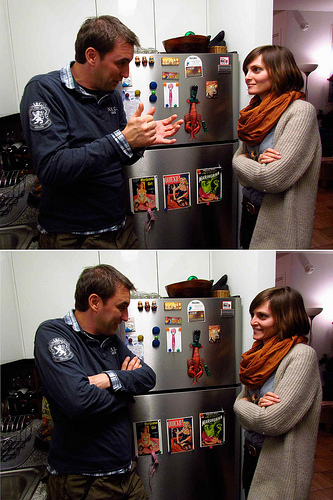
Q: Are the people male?
A: No, they are both male and female.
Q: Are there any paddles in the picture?
A: No, there are no paddles.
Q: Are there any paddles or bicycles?
A: No, there are no paddles or bicycles.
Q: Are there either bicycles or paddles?
A: No, there are no paddles or bicycles.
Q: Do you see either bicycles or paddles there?
A: No, there are no paddles or bicycles.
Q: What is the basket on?
A: The basket is on the freezer.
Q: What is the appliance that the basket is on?
A: The appliance is a refrigerator.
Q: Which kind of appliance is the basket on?
A: The basket is on the freezer.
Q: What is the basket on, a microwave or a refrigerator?
A: The basket is on a refrigerator.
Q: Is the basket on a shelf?
A: No, the basket is on a refrigerator.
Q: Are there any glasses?
A: No, there are no glasses.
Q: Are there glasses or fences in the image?
A: No, there are no glasses or fences.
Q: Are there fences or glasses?
A: No, there are no glasses or fences.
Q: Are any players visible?
A: No, there are no players.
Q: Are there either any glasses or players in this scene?
A: No, there are no players or glasses.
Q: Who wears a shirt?
A: The man wears a shirt.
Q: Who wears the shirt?
A: The man wears a shirt.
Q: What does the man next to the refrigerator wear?
A: The man wears a shirt.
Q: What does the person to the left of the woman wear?
A: The man wears a shirt.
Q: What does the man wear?
A: The man wears a shirt.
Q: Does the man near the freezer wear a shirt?
A: Yes, the man wears a shirt.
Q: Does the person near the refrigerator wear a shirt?
A: Yes, the man wears a shirt.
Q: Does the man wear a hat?
A: No, the man wears a shirt.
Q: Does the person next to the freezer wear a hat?
A: No, the man wears a shirt.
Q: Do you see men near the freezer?
A: Yes, there is a man near the freezer.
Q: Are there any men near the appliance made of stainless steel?
A: Yes, there is a man near the freezer.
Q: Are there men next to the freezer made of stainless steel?
A: Yes, there is a man next to the freezer.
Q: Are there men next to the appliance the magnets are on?
A: Yes, there is a man next to the freezer.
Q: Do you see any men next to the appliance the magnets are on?
A: Yes, there is a man next to the freezer.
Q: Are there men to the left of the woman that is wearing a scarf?
A: Yes, there is a man to the left of the woman.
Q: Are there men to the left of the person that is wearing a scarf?
A: Yes, there is a man to the left of the woman.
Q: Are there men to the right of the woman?
A: No, the man is to the left of the woman.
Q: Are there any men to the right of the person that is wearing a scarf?
A: No, the man is to the left of the woman.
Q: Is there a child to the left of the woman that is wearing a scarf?
A: No, there is a man to the left of the woman.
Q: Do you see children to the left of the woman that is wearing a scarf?
A: No, there is a man to the left of the woman.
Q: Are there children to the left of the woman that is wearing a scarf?
A: No, there is a man to the left of the woman.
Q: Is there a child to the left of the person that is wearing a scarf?
A: No, there is a man to the left of the woman.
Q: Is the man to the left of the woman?
A: Yes, the man is to the left of the woman.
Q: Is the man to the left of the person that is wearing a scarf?
A: Yes, the man is to the left of the woman.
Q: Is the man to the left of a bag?
A: No, the man is to the left of the woman.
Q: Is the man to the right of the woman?
A: No, the man is to the left of the woman.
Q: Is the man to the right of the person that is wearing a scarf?
A: No, the man is to the left of the woman.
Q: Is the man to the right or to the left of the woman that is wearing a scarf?
A: The man is to the left of the woman.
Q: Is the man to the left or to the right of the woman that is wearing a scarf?
A: The man is to the left of the woman.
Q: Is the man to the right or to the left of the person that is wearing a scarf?
A: The man is to the left of the woman.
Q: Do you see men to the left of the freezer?
A: Yes, there is a man to the left of the freezer.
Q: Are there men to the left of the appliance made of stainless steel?
A: Yes, there is a man to the left of the freezer.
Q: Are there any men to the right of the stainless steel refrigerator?
A: No, the man is to the left of the refrigerator.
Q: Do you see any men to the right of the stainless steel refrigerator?
A: No, the man is to the left of the refrigerator.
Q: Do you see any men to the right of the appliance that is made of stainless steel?
A: No, the man is to the left of the refrigerator.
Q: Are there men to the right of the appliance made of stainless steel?
A: No, the man is to the left of the refrigerator.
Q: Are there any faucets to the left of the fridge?
A: No, there is a man to the left of the fridge.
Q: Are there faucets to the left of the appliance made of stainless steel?
A: No, there is a man to the left of the fridge.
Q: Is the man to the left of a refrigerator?
A: Yes, the man is to the left of a refrigerator.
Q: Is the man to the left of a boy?
A: No, the man is to the left of a refrigerator.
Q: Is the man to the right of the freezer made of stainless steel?
A: No, the man is to the left of the fridge.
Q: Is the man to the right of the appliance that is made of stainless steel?
A: No, the man is to the left of the fridge.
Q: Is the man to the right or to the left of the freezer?
A: The man is to the left of the freezer.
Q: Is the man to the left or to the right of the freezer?
A: The man is to the left of the freezer.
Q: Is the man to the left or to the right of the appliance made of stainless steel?
A: The man is to the left of the freezer.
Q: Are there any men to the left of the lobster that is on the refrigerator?
A: Yes, there is a man to the left of the lobster.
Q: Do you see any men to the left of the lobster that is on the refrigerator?
A: Yes, there is a man to the left of the lobster.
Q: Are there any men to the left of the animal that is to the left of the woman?
A: Yes, there is a man to the left of the lobster.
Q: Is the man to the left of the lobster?
A: Yes, the man is to the left of the lobster.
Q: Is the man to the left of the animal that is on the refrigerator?
A: Yes, the man is to the left of the lobster.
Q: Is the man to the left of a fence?
A: No, the man is to the left of the lobster.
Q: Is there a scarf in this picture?
A: Yes, there is a scarf.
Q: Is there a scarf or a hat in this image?
A: Yes, there is a scarf.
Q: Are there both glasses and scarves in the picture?
A: No, there is a scarf but no glasses.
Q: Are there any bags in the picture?
A: No, there are no bags.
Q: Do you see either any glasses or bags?
A: No, there are no bags or glasses.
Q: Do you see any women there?
A: Yes, there is a woman.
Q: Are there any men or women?
A: Yes, there is a woman.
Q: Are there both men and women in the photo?
A: Yes, there are both a woman and a man.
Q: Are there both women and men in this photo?
A: Yes, there are both a woman and a man.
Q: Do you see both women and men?
A: Yes, there are both a woman and a man.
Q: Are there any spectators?
A: No, there are no spectators.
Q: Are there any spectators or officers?
A: No, there are no spectators or officers.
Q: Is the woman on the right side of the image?
A: Yes, the woman is on the right of the image.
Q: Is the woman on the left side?
A: No, the woman is on the right of the image.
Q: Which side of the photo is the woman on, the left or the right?
A: The woman is on the right of the image.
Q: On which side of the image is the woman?
A: The woman is on the right of the image.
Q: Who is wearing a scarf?
A: The woman is wearing a scarf.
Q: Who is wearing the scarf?
A: The woman is wearing a scarf.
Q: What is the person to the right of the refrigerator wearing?
A: The woman is wearing a scarf.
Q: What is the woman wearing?
A: The woman is wearing a scarf.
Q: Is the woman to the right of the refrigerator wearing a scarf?
A: Yes, the woman is wearing a scarf.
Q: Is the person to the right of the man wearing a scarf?
A: Yes, the woman is wearing a scarf.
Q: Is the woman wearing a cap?
A: No, the woman is wearing a scarf.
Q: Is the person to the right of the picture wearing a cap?
A: No, the woman is wearing a scarf.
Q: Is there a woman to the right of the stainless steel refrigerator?
A: Yes, there is a woman to the right of the fridge.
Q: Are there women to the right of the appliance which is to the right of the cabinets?
A: Yes, there is a woman to the right of the fridge.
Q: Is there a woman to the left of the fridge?
A: No, the woman is to the right of the fridge.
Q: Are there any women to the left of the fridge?
A: No, the woman is to the right of the fridge.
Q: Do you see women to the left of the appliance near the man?
A: No, the woman is to the right of the fridge.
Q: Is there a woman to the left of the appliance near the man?
A: No, the woman is to the right of the fridge.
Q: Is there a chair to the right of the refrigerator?
A: No, there is a woman to the right of the refrigerator.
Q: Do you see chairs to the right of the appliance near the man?
A: No, there is a woman to the right of the refrigerator.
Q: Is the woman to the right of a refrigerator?
A: Yes, the woman is to the right of a refrigerator.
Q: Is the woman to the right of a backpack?
A: No, the woman is to the right of a refrigerator.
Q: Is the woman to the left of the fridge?
A: No, the woman is to the right of the fridge.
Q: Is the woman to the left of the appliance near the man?
A: No, the woman is to the right of the fridge.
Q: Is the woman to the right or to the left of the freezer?
A: The woman is to the right of the freezer.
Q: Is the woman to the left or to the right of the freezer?
A: The woman is to the right of the freezer.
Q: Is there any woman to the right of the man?
A: Yes, there is a woman to the right of the man.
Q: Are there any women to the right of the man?
A: Yes, there is a woman to the right of the man.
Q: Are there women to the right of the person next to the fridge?
A: Yes, there is a woman to the right of the man.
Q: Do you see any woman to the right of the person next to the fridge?
A: Yes, there is a woman to the right of the man.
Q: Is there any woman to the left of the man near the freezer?
A: No, the woman is to the right of the man.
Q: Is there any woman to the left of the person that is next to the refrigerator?
A: No, the woman is to the right of the man.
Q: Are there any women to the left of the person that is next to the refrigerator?
A: No, the woman is to the right of the man.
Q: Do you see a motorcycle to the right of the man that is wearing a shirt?
A: No, there is a woman to the right of the man.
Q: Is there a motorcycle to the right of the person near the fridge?
A: No, there is a woman to the right of the man.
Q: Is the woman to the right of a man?
A: Yes, the woman is to the right of a man.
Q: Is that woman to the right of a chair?
A: No, the woman is to the right of a man.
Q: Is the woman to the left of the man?
A: No, the woman is to the right of the man.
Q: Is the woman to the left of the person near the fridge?
A: No, the woman is to the right of the man.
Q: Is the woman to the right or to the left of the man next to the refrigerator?
A: The woman is to the right of the man.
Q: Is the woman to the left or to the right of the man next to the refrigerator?
A: The woman is to the right of the man.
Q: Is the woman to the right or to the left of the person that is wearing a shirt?
A: The woman is to the right of the man.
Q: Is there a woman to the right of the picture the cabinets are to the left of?
A: Yes, there is a woman to the right of the picture.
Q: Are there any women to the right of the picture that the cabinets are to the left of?
A: Yes, there is a woman to the right of the picture.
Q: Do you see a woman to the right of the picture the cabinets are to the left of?
A: Yes, there is a woman to the right of the picture.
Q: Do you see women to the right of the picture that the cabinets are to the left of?
A: Yes, there is a woman to the right of the picture.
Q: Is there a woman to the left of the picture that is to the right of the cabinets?
A: No, the woman is to the right of the picture.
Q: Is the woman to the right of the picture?
A: Yes, the woman is to the right of the picture.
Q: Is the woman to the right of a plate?
A: No, the woman is to the right of the picture.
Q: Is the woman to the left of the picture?
A: No, the woman is to the right of the picture.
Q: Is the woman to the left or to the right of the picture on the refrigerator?
A: The woman is to the right of the picture.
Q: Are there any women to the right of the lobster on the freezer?
A: Yes, there is a woman to the right of the lobster.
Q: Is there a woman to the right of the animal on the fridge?
A: Yes, there is a woman to the right of the lobster.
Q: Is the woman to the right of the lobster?
A: Yes, the woman is to the right of the lobster.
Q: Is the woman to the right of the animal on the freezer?
A: Yes, the woman is to the right of the lobster.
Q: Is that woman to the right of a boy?
A: No, the woman is to the right of the lobster.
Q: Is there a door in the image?
A: Yes, there is a door.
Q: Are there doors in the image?
A: Yes, there is a door.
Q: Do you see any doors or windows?
A: Yes, there is a door.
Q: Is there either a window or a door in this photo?
A: Yes, there is a door.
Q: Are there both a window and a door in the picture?
A: No, there is a door but no windows.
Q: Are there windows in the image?
A: No, there are no windows.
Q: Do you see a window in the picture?
A: No, there are no windows.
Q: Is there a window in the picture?
A: No, there are no windows.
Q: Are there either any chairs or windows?
A: No, there are no windows or chairs.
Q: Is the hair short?
A: Yes, the hair is short.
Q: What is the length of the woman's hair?
A: The hair is short.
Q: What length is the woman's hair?
A: The hair is short.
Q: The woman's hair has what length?
A: The hair is short.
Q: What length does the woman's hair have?
A: The hair has short length.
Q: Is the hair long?
A: No, the hair is short.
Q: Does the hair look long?
A: No, the hair is short.